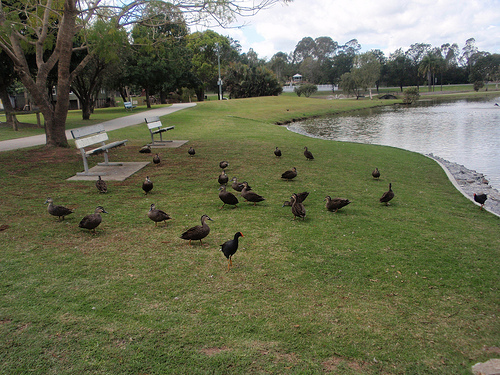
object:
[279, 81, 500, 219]
water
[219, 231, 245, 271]
duck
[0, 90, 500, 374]
grass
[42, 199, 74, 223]
ducks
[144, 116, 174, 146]
bench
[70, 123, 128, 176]
bench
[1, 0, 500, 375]
park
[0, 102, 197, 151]
walking path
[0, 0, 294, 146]
tree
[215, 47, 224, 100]
light pole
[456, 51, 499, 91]
trees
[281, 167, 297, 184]
duck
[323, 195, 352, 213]
duck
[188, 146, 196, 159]
duck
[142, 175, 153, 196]
duck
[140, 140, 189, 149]
slab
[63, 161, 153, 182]
slab